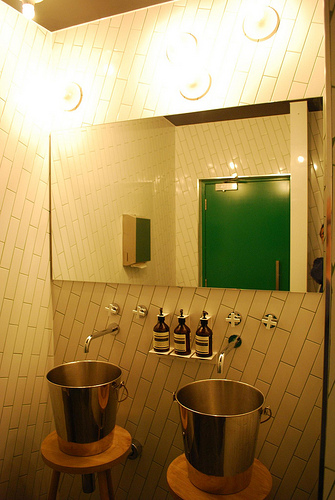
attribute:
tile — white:
[280, 313, 302, 367]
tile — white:
[265, 362, 288, 418]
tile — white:
[290, 374, 318, 432]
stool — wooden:
[39, 432, 130, 498]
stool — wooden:
[168, 467, 271, 499]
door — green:
[194, 174, 305, 292]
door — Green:
[197, 180, 293, 291]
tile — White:
[50, 284, 314, 498]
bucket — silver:
[171, 374, 277, 492]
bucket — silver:
[41, 357, 128, 452]